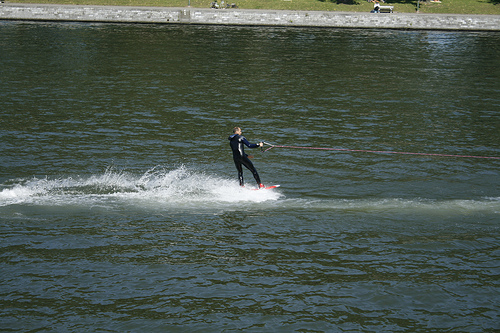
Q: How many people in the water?
A: One.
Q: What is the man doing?
A: Jet skiing.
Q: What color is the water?
A: Green.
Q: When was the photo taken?
A: Day time.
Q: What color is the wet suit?
A: Black.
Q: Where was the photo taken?
A: Near water.